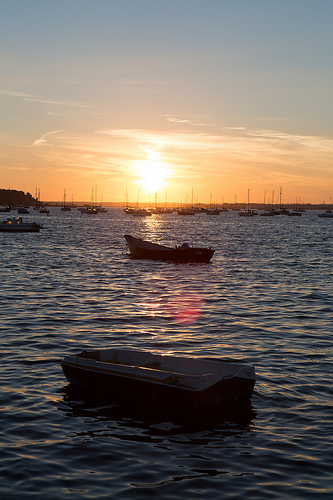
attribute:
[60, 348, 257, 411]
boat — nearest, small, white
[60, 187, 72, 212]
sailboat — distant, sailless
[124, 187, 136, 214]
sailboat — distant, sailless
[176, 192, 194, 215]
sailboat — distant, sailless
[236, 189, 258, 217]
sailboat — distant, sailless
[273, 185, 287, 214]
sailboat — distant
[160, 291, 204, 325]
lens flare — red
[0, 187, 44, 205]
hill — distant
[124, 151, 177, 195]
sun — setting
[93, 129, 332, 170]
cloud — white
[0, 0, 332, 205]
sky — blue, multicolored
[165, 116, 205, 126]
cloud — white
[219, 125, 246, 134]
cloud — white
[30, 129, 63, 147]
cloud — white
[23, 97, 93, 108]
cloud — white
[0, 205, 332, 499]
water — clear, blue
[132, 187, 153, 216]
sailboat — distant, sailless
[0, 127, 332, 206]
sunset — orange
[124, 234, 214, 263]
boat — small, silhouetted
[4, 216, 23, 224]
cabin — lit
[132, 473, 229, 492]
ripple — small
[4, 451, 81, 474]
ripple — small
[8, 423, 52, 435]
ripple — small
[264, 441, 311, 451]
ripple — small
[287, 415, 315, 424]
ripple — small